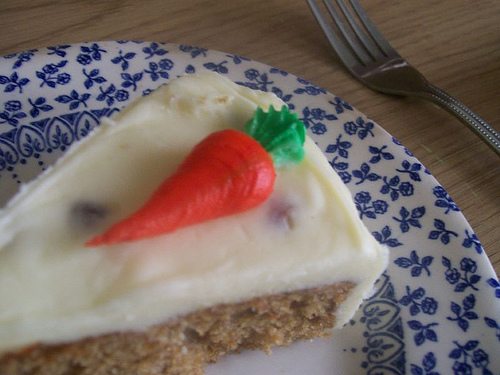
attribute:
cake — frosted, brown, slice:
[2, 71, 389, 369]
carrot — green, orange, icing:
[87, 111, 305, 250]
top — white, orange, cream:
[0, 76, 383, 353]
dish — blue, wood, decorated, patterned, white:
[1, 39, 499, 374]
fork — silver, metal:
[308, 3, 499, 159]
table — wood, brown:
[6, 5, 500, 275]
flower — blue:
[34, 60, 76, 91]